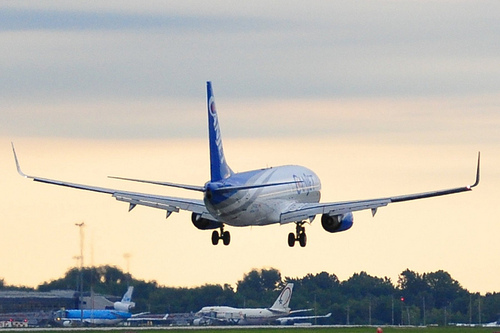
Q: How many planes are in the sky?
A: One.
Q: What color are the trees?
A: Green.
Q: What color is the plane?
A: White and blue.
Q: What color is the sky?
A: Cream and gray.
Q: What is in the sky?
A: The plane.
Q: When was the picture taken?
A: Daytime.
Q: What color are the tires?
A: Black.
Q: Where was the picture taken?
A: At an airport.